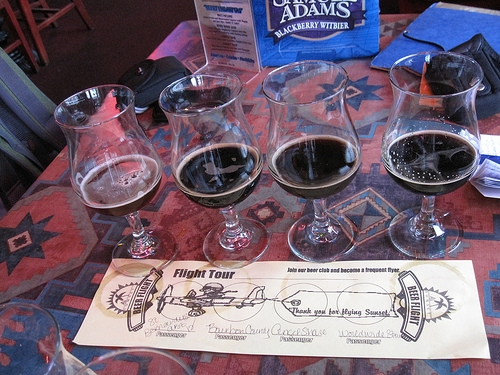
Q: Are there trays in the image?
A: No, there are no trays.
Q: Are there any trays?
A: No, there are no trays.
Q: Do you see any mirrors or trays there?
A: No, there are no trays or mirrors.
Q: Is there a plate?
A: No, there are no plates.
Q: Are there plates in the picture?
A: No, there are no plates.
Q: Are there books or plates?
A: No, there are no plates or books.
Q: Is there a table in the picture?
A: Yes, there is a table.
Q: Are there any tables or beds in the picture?
A: Yes, there is a table.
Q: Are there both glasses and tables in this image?
A: Yes, there are both a table and glasses.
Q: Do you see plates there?
A: No, there are no plates.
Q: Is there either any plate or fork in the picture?
A: No, there are no plates or forks.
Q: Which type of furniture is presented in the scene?
A: The furniture is a table.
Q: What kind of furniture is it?
A: The piece of furniture is a table.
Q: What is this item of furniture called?
A: That is a table.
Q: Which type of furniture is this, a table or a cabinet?
A: That is a table.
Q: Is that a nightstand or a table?
A: That is a table.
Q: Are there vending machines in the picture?
A: No, there are no vending machines.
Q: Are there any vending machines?
A: No, there are no vending machines.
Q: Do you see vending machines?
A: No, there are no vending machines.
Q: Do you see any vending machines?
A: No, there are no vending machines.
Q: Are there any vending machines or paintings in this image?
A: No, there are no vending machines or paintings.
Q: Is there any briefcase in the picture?
A: No, there are no briefcases.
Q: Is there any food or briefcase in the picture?
A: No, there are no briefcases or food.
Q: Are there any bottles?
A: No, there are no bottles.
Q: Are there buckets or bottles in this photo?
A: No, there are no bottles or buckets.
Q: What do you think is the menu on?
A: The menu is on the table.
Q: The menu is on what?
A: The menu is on the table.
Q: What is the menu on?
A: The menu is on the table.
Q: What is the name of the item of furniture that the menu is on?
A: The piece of furniture is a table.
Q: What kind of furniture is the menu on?
A: The menu is on the table.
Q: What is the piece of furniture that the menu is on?
A: The piece of furniture is a table.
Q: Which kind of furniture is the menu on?
A: The menu is on the table.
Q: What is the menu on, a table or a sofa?
A: The menu is on a table.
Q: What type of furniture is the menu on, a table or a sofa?
A: The menu is on a table.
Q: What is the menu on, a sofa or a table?
A: The menu is on a table.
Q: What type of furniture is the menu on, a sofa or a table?
A: The menu is on a table.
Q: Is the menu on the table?
A: Yes, the menu is on the table.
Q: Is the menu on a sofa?
A: No, the menu is on the table.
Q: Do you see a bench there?
A: No, there are no benches.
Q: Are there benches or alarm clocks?
A: No, there are no benches or alarm clocks.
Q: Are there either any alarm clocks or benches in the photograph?
A: No, there are no benches or alarm clocks.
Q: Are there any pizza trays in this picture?
A: No, there are no pizza trays.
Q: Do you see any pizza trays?
A: No, there are no pizza trays.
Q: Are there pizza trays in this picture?
A: No, there are no pizza trays.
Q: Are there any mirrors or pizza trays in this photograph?
A: No, there are no pizza trays or mirrors.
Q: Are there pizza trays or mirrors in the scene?
A: No, there are no pizza trays or mirrors.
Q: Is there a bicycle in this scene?
A: No, there are no bicycles.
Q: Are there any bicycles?
A: No, there are no bicycles.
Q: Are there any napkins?
A: No, there are no napkins.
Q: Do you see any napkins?
A: No, there are no napkins.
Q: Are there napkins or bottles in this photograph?
A: No, there are no napkins or bottles.